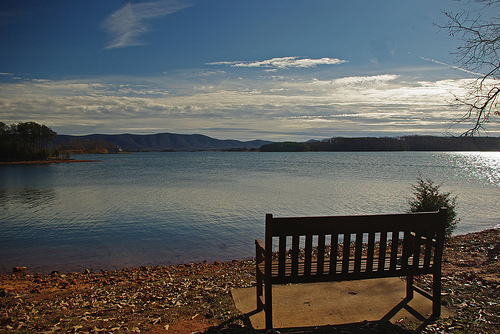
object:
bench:
[255, 207, 448, 329]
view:
[2, 73, 498, 277]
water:
[0, 152, 500, 275]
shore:
[0, 226, 500, 281]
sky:
[6, 1, 496, 122]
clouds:
[3, 0, 498, 142]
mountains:
[0, 121, 499, 161]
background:
[0, 0, 500, 164]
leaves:
[0, 228, 500, 334]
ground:
[2, 263, 498, 334]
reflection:
[0, 185, 59, 225]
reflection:
[452, 151, 497, 169]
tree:
[403, 170, 465, 239]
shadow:
[197, 297, 437, 334]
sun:
[439, 64, 492, 105]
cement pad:
[231, 277, 458, 330]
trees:
[0, 121, 57, 158]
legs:
[407, 273, 442, 315]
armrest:
[255, 239, 265, 264]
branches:
[432, 0, 500, 149]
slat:
[278, 236, 286, 276]